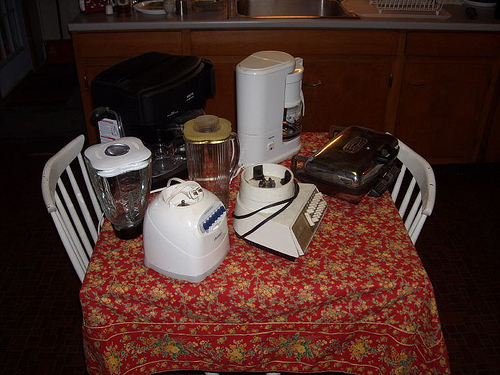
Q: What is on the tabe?
A: Appliances.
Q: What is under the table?
A: Chair.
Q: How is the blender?
A: Base with cord.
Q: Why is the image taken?
A: Remembrance.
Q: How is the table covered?
A: Cloth.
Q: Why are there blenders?
A: Chop up food.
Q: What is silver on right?
A: Waffle maker.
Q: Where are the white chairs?
A: Sides of table.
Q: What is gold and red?
A: Tablecloth.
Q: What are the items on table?
A: Appliances.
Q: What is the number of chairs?
A: Two.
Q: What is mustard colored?
A: Top of blender.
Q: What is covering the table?
A: Cloth.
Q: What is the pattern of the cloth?
A: Paisley.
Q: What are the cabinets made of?
A: Wood.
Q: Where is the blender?
A: Table.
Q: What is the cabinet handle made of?
A: Metal.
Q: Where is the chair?
A: Under the table.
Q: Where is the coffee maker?
A: Table.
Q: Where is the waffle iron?
A: Table.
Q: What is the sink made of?
A: Metal.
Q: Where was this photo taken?
A: Kitchen.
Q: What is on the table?
A: Small appliances.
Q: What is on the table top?
A: Table cloth.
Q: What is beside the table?
A: Chair.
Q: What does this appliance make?
A: Coffee.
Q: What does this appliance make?
A: Waffles.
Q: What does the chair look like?
A: White.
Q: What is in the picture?
A: Kitchen appliances.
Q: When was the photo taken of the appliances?
A: Nighttime.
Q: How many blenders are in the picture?
A: Two.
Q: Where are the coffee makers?
A: On the table.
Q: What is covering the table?
A: Tablecloth.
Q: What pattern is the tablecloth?
A: Floral.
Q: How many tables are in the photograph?
A: One.